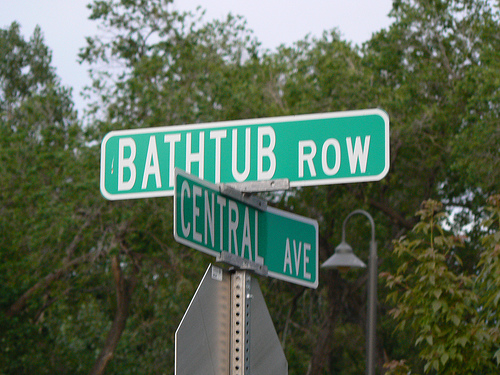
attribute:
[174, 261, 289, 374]
stop sign — silver, turned to rear, backwards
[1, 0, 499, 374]
trees — green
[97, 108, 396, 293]
street sign — green, white, together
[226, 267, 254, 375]
pole — grey, with holes, metal, long, silver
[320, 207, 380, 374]
lights pole — grey, metal, curved at the top, overhead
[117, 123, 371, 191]
words — white, bathtub row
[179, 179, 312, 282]
words — central ave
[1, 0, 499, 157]
sky — blue, grey, gray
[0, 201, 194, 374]
tree trunk — long, brown